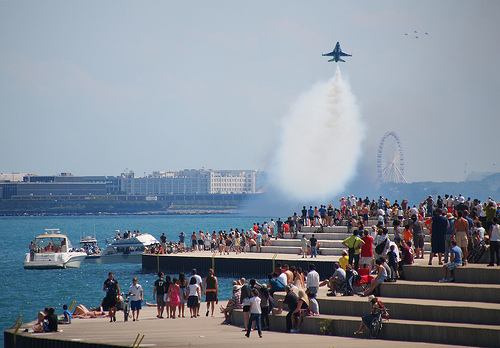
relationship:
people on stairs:
[143, 201, 337, 259] [143, 214, 499, 274]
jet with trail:
[320, 36, 356, 64] [268, 64, 366, 203]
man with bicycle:
[129, 274, 144, 321] [119, 290, 134, 325]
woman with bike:
[352, 293, 381, 335] [367, 305, 387, 339]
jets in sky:
[402, 27, 431, 42] [2, 2, 500, 184]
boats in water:
[23, 226, 159, 270] [2, 215, 294, 347]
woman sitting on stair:
[352, 293, 381, 335] [229, 302, 499, 348]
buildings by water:
[1, 167, 272, 199] [2, 215, 294, 347]